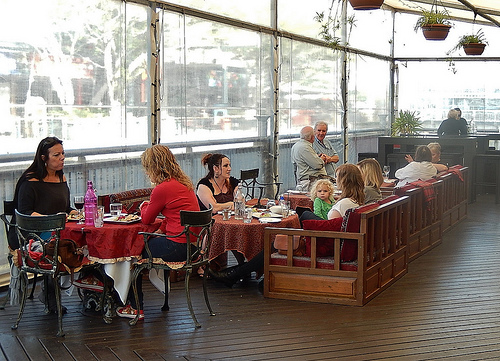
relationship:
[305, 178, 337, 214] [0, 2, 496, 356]
child in restaurant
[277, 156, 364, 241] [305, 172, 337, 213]
woman holding child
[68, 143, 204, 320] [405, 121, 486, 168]
lady at table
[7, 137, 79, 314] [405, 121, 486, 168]
lady at table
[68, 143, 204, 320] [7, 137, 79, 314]
lady facing lady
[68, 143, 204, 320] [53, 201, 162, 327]
lady sitting at table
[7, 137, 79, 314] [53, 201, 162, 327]
lady sitting at table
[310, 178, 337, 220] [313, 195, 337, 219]
child wearing green shirt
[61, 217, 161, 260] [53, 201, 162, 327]
red tablecloth on table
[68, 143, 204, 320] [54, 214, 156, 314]
lady sitting at table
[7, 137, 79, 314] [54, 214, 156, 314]
lady sitting at table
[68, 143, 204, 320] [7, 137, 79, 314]
lady across from lady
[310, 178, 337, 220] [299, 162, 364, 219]
child sitting with woman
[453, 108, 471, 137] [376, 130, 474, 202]
person behind dark counter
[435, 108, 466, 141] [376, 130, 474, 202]
person behind dark counter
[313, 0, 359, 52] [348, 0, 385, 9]
plant in planter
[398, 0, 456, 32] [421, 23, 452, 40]
plant in planter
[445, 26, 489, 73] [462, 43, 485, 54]
plant in planter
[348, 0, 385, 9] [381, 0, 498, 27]
planter hanging from ceiling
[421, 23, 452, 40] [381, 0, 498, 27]
planter hanging from ceiling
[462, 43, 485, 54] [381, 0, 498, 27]
planter hanging from ceiling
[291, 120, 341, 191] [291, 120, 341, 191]
men talking with men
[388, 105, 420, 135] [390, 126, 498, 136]
plant on ledge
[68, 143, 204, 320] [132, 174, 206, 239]
lady wearing shirt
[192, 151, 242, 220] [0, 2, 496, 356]
diner on restaurant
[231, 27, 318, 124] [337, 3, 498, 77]
plants in pots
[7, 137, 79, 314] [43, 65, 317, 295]
lady in setting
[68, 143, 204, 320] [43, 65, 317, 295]
lady in setting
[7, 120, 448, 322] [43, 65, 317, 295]
people in setting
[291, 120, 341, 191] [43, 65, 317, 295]
men in setting